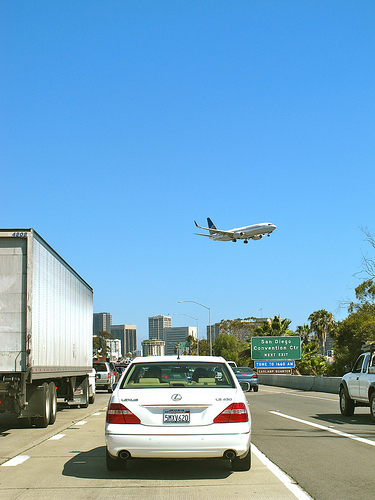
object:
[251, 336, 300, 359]
sign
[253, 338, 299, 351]
san diego convention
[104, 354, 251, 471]
car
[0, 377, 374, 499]
highway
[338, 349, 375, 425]
truck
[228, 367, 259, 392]
car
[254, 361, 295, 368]
street sign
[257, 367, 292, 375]
street sign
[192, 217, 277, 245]
airplane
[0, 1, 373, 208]
sky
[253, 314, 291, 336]
palm tree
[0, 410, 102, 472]
line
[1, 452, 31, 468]
hash mark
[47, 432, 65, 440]
hash mark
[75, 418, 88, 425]
hash mark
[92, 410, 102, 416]
hash mark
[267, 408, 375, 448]
line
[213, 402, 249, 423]
tail light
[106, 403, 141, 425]
tail light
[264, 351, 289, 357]
next right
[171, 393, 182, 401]
lexus symbol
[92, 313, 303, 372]
city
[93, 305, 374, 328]
skyline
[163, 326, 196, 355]
building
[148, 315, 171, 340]
building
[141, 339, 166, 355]
building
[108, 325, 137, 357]
building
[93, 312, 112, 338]
building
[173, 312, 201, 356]
street light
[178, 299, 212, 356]
street light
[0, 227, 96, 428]
truck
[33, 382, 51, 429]
tire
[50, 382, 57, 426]
tire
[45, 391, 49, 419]
rim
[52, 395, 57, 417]
rim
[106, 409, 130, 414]
light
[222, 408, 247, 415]
light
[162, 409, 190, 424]
license plate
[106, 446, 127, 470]
tire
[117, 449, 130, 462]
exhaust